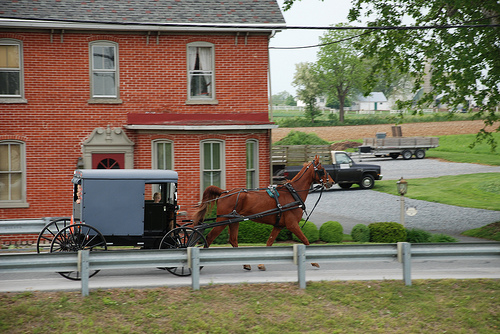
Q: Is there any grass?
A: Yes, there is grass.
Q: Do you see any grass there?
A: Yes, there is grass.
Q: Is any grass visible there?
A: Yes, there is grass.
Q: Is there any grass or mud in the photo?
A: Yes, there is grass.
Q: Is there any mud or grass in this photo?
A: Yes, there is grass.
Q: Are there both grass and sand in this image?
A: No, there is grass but no sand.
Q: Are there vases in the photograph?
A: No, there are no vases.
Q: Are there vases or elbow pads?
A: No, there are no vases or elbow pads.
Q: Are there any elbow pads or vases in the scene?
A: No, there are no vases or elbow pads.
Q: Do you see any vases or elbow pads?
A: No, there are no vases or elbow pads.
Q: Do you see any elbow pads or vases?
A: No, there are no vases or elbow pads.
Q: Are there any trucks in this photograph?
A: Yes, there is a truck.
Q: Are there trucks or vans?
A: Yes, there is a truck.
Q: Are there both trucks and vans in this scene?
A: No, there is a truck but no vans.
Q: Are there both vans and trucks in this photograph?
A: No, there is a truck but no vans.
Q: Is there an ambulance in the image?
A: No, there are no ambulances.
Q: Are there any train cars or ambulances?
A: No, there are no ambulances or train cars.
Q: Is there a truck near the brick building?
A: Yes, there is a truck near the building.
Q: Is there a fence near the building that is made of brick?
A: No, there is a truck near the building.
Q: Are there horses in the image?
A: Yes, there is a horse.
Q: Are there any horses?
A: Yes, there is a horse.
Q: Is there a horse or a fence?
A: Yes, there is a horse.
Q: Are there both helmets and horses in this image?
A: No, there is a horse but no helmets.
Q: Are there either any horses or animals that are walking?
A: Yes, the horse is walking.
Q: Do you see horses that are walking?
A: Yes, there is a horse that is walking.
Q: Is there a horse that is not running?
A: Yes, there is a horse that is walking.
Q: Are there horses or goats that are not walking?
A: No, there is a horse but it is walking.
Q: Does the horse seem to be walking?
A: Yes, the horse is walking.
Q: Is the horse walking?
A: Yes, the horse is walking.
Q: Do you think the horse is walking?
A: Yes, the horse is walking.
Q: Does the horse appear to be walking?
A: Yes, the horse is walking.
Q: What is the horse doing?
A: The horse is walking.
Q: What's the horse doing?
A: The horse is walking.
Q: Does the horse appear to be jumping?
A: No, the horse is walking.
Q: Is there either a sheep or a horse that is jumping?
A: No, there is a horse but it is walking.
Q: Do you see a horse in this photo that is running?
A: No, there is a horse but it is walking.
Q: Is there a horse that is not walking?
A: No, there is a horse but it is walking.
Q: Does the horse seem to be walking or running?
A: The horse is walking.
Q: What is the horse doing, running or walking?
A: The horse is walking.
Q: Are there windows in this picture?
A: Yes, there is a window.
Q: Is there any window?
A: Yes, there is a window.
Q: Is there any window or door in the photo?
A: Yes, there is a window.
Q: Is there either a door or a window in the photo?
A: Yes, there is a window.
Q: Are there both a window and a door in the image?
A: Yes, there are both a window and a door.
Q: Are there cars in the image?
A: No, there are no cars.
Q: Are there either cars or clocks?
A: No, there are no cars or clocks.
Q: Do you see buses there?
A: No, there are no buses.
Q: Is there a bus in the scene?
A: No, there are no buses.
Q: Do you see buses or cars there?
A: No, there are no buses or cars.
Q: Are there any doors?
A: Yes, there is a door.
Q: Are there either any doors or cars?
A: Yes, there is a door.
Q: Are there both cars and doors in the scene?
A: No, there is a door but no cars.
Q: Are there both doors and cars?
A: No, there is a door but no cars.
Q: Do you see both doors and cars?
A: No, there is a door but no cars.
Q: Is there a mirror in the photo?
A: No, there are no mirrors.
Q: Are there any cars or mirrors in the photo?
A: No, there are no mirrors or cars.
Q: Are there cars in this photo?
A: No, there are no cars.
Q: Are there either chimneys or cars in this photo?
A: No, there are no cars or chimneys.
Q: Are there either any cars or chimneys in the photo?
A: No, there are no cars or chimneys.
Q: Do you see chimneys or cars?
A: No, there are no cars or chimneys.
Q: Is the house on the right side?
A: Yes, the house is on the right of the image.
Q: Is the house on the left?
A: No, the house is on the right of the image.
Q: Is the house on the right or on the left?
A: The house is on the right of the image.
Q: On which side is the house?
A: The house is on the right of the image.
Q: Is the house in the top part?
A: Yes, the house is in the top of the image.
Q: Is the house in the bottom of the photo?
A: No, the house is in the top of the image.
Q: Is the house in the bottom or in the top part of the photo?
A: The house is in the top of the image.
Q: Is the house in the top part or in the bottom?
A: The house is in the top of the image.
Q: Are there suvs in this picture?
A: No, there are no suvs.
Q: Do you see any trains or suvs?
A: No, there are no suvs or trains.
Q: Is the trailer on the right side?
A: Yes, the trailer is on the right of the image.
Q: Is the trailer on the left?
A: No, the trailer is on the right of the image.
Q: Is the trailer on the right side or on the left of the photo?
A: The trailer is on the right of the image.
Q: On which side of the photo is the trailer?
A: The trailer is on the right of the image.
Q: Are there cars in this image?
A: No, there are no cars.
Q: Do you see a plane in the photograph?
A: No, there are no airplanes.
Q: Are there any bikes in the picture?
A: No, there are no bikes.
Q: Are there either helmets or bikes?
A: No, there are no bikes or helmets.